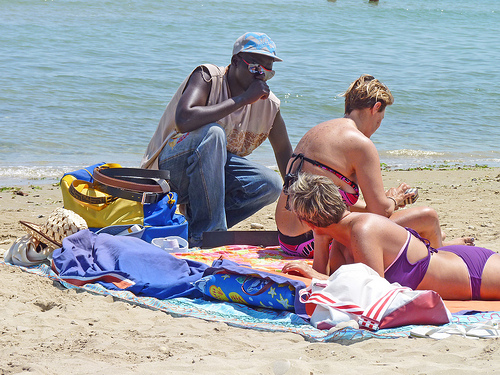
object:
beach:
[3, 151, 499, 374]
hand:
[243, 74, 271, 103]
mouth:
[251, 76, 272, 92]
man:
[142, 32, 290, 260]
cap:
[230, 30, 283, 61]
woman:
[275, 72, 441, 256]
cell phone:
[397, 176, 418, 207]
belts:
[69, 166, 163, 210]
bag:
[61, 161, 191, 241]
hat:
[15, 206, 86, 250]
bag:
[298, 263, 454, 327]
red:
[409, 305, 437, 323]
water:
[2, 0, 499, 162]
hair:
[284, 170, 349, 227]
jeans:
[158, 135, 282, 244]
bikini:
[384, 228, 495, 297]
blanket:
[8, 233, 52, 277]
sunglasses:
[226, 48, 277, 80]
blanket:
[90, 273, 493, 343]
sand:
[5, 270, 499, 373]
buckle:
[140, 189, 156, 203]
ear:
[372, 99, 380, 114]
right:
[348, 74, 444, 238]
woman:
[290, 171, 499, 303]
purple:
[392, 263, 419, 283]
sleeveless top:
[140, 61, 285, 175]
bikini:
[278, 153, 360, 263]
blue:
[150, 211, 175, 235]